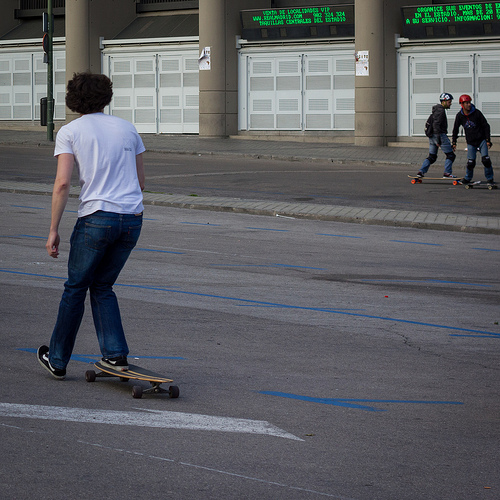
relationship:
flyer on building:
[354, 49, 369, 76] [0, 0, 498, 152]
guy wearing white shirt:
[36, 70, 146, 378] [53, 113, 146, 218]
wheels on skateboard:
[123, 381, 184, 401] [78, 354, 188, 405]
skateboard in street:
[78, 354, 188, 405] [5, 172, 497, 499]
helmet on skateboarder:
[456, 95, 473, 106] [451, 94, 498, 184]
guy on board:
[36, 70, 146, 378] [81, 347, 183, 409]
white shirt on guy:
[53, 115, 147, 218] [36, 70, 146, 378]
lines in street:
[252, 381, 463, 415] [5, 172, 497, 499]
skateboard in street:
[83, 360, 179, 398] [9, 219, 499, 466]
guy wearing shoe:
[36, 70, 146, 378] [33, 342, 70, 384]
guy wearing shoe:
[36, 70, 146, 378] [94, 349, 134, 374]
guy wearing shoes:
[36, 70, 146, 378] [41, 347, 126, 381]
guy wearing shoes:
[36, 70, 146, 378] [33, 345, 131, 383]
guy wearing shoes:
[36, 70, 146, 378] [31, 328, 127, 385]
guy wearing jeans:
[36, 70, 146, 378] [416, 132, 458, 179]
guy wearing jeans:
[36, 70, 146, 378] [463, 140, 494, 187]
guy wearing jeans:
[36, 70, 146, 378] [24, 207, 150, 381]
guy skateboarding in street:
[44, 87, 146, 335] [212, 282, 342, 448]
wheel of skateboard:
[85, 367, 98, 384] [88, 358, 184, 406]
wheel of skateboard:
[451, 180, 460, 185] [409, 174, 464, 186]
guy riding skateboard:
[36, 70, 146, 378] [86, 360, 176, 395]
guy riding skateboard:
[36, 70, 146, 378] [400, 167, 470, 192]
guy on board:
[36, 70, 146, 378] [87, 350, 184, 403]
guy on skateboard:
[36, 70, 146, 378] [83, 356, 180, 401]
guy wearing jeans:
[36, 70, 146, 378] [47, 209, 144, 364]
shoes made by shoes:
[29, 340, 133, 379] [34, 344, 67, 377]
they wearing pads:
[420, 81, 482, 163] [426, 151, 456, 164]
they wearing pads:
[420, 81, 482, 163] [467, 154, 493, 171]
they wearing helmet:
[420, 81, 482, 163] [438, 92, 454, 102]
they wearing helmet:
[420, 81, 482, 163] [462, 92, 473, 108]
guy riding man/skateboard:
[36, 70, 146, 378] [404, 93, 466, 183]